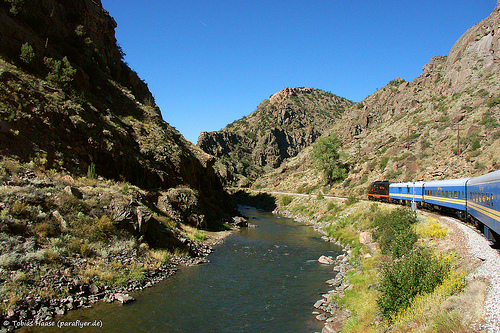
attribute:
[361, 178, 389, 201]
locomotive — black, orange, red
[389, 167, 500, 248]
cars — white, blue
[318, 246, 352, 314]
rocks — small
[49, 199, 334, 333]
stream — curved, dark green, small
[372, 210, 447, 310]
shrub brush — tiny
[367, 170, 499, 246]
train — moving, blue, black, curving, yellow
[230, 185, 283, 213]
shadow — cast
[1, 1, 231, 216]
hill — rocky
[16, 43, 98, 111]
bushes — green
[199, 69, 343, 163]
hill — distant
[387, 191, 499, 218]
stripe — yellow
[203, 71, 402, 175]
mountain — covered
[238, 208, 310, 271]
water — murky, blue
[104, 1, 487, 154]
sky — clear, blue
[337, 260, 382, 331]
grass — green